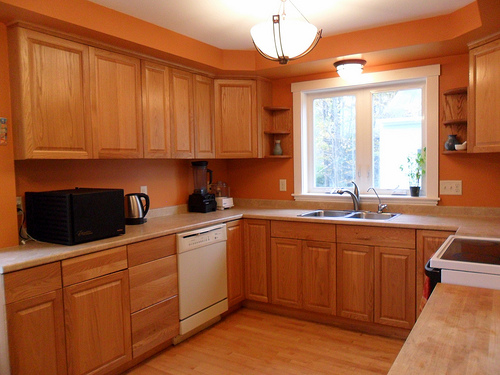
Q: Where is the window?
A: It is over the kitchen sink.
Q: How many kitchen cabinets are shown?
A: There are five.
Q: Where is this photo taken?
A: Kitchen.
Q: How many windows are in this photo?
A: One.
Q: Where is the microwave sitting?
A: On the countertop.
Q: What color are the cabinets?
A: Brown.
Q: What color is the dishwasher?
A: White.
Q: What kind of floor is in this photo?
A: Hardwood.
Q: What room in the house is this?
A: Kitchen.